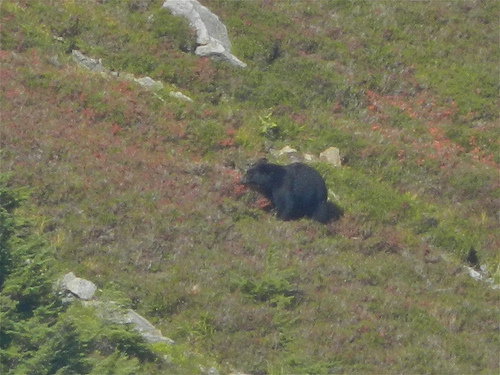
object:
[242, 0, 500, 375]
grass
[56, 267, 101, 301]
stone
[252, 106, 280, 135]
plant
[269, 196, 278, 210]
leg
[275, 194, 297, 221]
leg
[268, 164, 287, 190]
neck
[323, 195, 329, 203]
tail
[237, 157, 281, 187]
head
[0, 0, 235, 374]
grass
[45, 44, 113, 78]
rocks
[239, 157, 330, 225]
bear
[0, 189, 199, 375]
bushes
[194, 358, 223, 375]
rock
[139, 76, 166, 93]
rock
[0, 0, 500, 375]
hill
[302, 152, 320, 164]
rock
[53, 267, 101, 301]
rock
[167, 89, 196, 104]
rock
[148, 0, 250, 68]
rock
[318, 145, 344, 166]
rock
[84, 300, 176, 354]
rock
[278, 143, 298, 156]
rock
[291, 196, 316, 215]
stomach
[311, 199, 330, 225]
leg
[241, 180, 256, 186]
mouth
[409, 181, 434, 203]
plant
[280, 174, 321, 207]
black